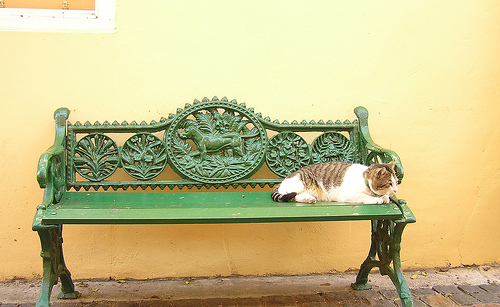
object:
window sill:
[0, 0, 113, 33]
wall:
[0, 0, 499, 285]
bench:
[31, 95, 417, 307]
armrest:
[31, 107, 72, 229]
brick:
[136, 298, 171, 307]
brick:
[408, 286, 440, 299]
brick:
[450, 294, 481, 307]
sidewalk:
[0, 263, 499, 307]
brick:
[366, 298, 396, 307]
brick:
[294, 293, 327, 306]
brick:
[0, 302, 20, 307]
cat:
[270, 160, 397, 205]